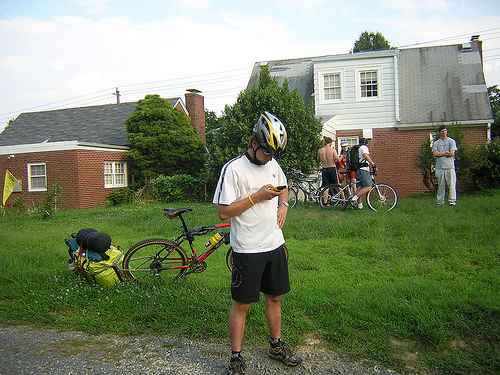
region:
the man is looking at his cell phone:
[216, 108, 311, 367]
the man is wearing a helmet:
[253, 111, 288, 156]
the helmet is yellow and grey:
[251, 109, 287, 149]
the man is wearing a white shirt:
[210, 150, 291, 257]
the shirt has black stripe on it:
[212, 148, 246, 203]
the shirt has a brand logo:
[271, 171, 278, 179]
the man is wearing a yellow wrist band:
[246, 192, 256, 209]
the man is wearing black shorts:
[228, 245, 291, 305]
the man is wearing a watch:
[278, 198, 289, 208]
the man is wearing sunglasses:
[259, 146, 276, 158]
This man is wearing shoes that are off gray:
[268, 340, 290, 369]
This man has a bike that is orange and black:
[149, 222, 214, 302]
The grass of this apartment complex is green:
[376, 242, 406, 290]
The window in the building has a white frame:
[25, 172, 50, 202]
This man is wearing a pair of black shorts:
[234, 247, 301, 313]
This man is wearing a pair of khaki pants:
[435, 170, 480, 221]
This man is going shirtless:
[318, 152, 336, 167]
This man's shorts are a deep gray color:
[360, 170, 380, 197]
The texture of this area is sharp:
[123, 356, 134, 373]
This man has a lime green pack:
[99, 266, 119, 284]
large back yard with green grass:
[2, 198, 487, 333]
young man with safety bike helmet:
[194, 133, 325, 353]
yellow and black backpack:
[32, 218, 164, 289]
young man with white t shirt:
[190, 141, 322, 281]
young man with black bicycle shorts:
[185, 221, 301, 344]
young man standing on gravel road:
[0, 107, 388, 369]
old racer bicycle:
[102, 193, 285, 319]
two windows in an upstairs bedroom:
[282, 58, 442, 149]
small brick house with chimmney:
[0, 84, 218, 226]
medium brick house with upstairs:
[232, 33, 482, 215]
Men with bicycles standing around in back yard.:
[313, 130, 408, 219]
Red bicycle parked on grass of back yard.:
[121, 203, 233, 298]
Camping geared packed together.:
[56, 223, 133, 291]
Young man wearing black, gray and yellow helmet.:
[246, 106, 293, 161]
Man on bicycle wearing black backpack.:
[341, 131, 399, 216]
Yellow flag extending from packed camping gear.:
[3, 166, 83, 248]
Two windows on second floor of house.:
[311, 59, 409, 121]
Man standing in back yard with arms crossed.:
[416, 117, 471, 210]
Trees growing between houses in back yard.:
[125, 86, 322, 202]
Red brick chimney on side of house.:
[181, 88, 211, 153]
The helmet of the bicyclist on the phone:
[252, 108, 291, 158]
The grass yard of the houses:
[0, 196, 497, 373]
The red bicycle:
[121, 200, 294, 285]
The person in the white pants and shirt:
[427, 125, 465, 205]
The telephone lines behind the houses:
[0, 21, 498, 120]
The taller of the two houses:
[235, 38, 492, 200]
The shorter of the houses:
[0, 93, 212, 215]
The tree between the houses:
[112, 65, 209, 207]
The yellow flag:
[0, 172, 20, 207]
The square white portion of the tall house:
[310, 52, 400, 128]